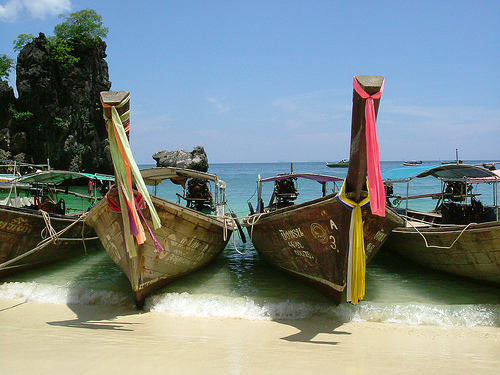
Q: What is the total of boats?
A: Two.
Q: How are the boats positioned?
A: Parked.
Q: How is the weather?
A: Bright sky.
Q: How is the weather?
A: A few clouds.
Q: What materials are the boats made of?
A: Wood.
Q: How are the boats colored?
A: Brown.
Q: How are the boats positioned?
A: In a row.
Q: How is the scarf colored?
A: Multicolored.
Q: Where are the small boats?
A: On the shore.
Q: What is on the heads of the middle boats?
A: Scarves.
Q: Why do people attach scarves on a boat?
A: To decorate the boat.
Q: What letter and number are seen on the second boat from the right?
A: A 3.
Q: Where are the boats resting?
A: The beach.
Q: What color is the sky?
A: Blue.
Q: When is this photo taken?
A: Daytime.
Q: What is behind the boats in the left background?
A: Trees.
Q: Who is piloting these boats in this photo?
A: No one.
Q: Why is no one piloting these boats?
A: They are beached.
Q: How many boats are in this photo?
A: Four.